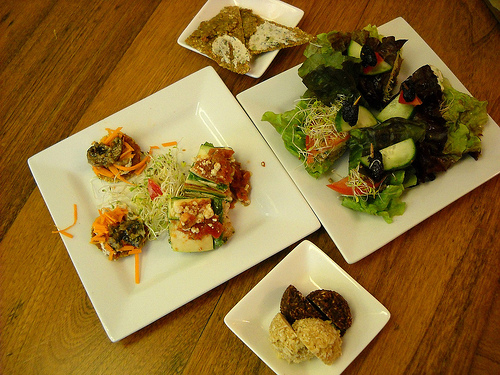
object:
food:
[259, 23, 490, 224]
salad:
[89, 204, 151, 263]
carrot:
[51, 204, 77, 238]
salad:
[108, 156, 211, 241]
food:
[176, 141, 250, 203]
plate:
[28, 65, 321, 345]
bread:
[185, 5, 315, 74]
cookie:
[279, 284, 353, 338]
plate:
[235, 17, 498, 265]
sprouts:
[280, 98, 348, 169]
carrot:
[88, 206, 128, 245]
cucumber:
[378, 138, 416, 173]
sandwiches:
[165, 140, 253, 253]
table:
[0, 1, 181, 82]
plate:
[176, 0, 305, 79]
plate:
[223, 239, 392, 374]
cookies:
[267, 317, 342, 366]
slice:
[167, 221, 213, 253]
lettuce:
[340, 171, 417, 225]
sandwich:
[368, 68, 440, 130]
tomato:
[305, 128, 349, 164]